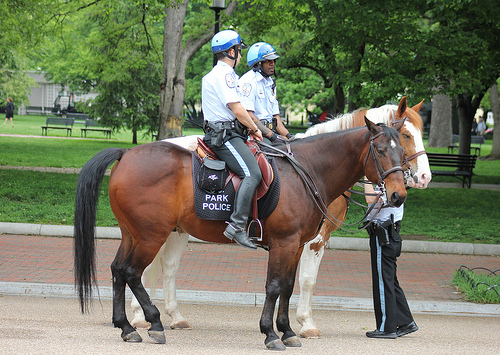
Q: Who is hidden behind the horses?
A: Police officer.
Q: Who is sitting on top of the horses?
A: Policemen.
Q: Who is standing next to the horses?
A: Policeman.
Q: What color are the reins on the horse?
A: Black.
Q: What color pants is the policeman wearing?
A: Black pants with blue stripe.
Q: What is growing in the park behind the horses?
A: Trees.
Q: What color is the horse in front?
A: Brown.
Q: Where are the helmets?
A: On the police officers' heads.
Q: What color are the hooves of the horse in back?
A: White.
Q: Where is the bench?
A: Under a tree.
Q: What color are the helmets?
A: Blue and white.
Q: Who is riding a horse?
A: A police officer.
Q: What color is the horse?
A: Brown with white legs.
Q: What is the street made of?
A: Red brick.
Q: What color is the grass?
A: Green.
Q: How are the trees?
A: Full and green.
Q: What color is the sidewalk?
A: Gray.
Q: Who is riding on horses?
A: The policemen.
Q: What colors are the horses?
A: Brown and white.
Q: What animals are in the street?
A: Horses.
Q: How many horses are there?
A: Two.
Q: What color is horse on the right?
A: White.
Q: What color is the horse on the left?
A: Brown.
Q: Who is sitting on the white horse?
A: A policeman.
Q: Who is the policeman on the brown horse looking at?
A: Man standing.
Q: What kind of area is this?
A: A park.